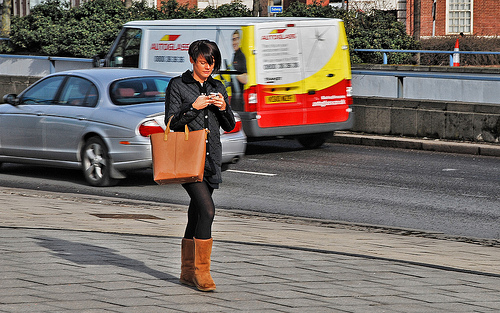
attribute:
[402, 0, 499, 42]
building — red, brick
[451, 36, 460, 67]
cone — orange, white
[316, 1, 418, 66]
bushes — green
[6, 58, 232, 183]
car — grey 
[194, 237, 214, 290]
boot — tan 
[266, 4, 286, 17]
street sign — blue , white 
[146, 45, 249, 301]
lady — light skinned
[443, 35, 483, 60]
fence railing — blue, metal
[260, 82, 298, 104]
license plate — yellow, black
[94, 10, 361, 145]
van — white, yellow 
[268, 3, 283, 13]
sign — blue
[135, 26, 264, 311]
lady — long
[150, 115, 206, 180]
bag — brown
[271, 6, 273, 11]
letter — white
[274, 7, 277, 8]
letter — white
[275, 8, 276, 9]
letter — white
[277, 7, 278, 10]
letter — white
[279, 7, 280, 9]
letter — white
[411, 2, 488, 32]
wall — brown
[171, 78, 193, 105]
coat — black